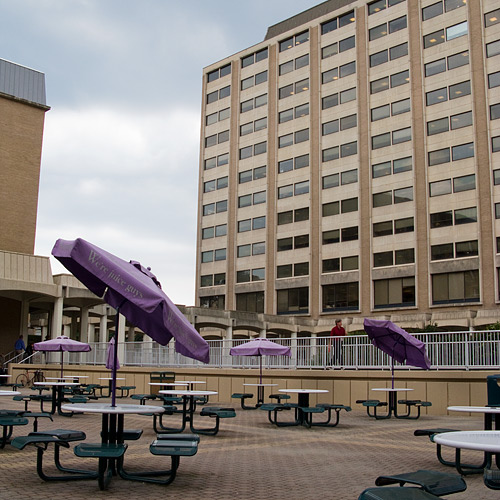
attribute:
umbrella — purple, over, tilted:
[49, 213, 258, 363]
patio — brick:
[111, 337, 498, 455]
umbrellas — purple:
[64, 256, 437, 403]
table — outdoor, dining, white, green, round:
[58, 397, 176, 449]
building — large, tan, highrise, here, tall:
[208, 83, 490, 296]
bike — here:
[18, 360, 69, 396]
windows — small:
[258, 99, 447, 178]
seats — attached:
[49, 407, 223, 469]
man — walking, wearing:
[317, 283, 376, 386]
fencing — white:
[240, 323, 356, 384]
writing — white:
[82, 245, 152, 304]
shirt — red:
[332, 307, 355, 357]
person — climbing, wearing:
[0, 313, 61, 394]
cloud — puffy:
[62, 26, 225, 151]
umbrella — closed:
[75, 326, 148, 377]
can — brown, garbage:
[134, 364, 230, 433]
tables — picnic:
[60, 370, 408, 490]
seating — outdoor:
[167, 381, 452, 469]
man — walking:
[13, 324, 100, 385]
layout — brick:
[171, 407, 435, 487]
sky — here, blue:
[49, 12, 216, 267]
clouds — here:
[75, 21, 286, 65]